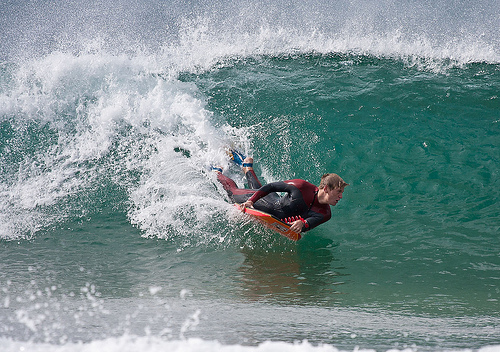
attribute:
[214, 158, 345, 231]
man — surfing, wet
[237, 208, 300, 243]
surf board — orange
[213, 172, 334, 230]
wet suit — red, black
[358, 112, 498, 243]
water — green\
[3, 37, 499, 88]
waves — white, green, crashing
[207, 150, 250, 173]
footstraps — blue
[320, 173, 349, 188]
hair — wet